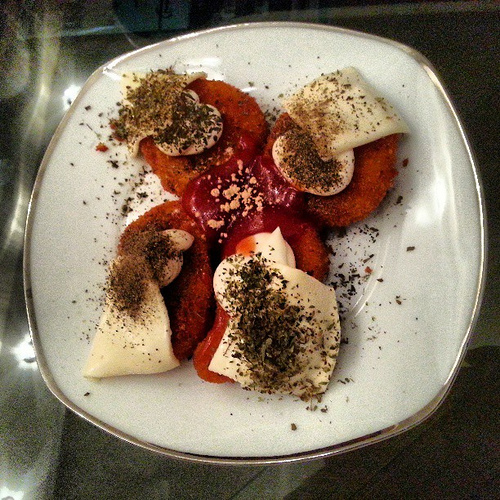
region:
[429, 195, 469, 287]
this is a plate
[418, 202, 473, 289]
the plate is glass like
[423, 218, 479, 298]
the plate is white incolor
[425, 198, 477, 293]
the plate is flat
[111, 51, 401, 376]
this is food on the plate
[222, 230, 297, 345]
the cream is white in color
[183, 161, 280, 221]
the spice is red in color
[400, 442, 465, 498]
this is the table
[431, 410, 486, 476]
the table is grey in color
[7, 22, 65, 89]
the table is glass like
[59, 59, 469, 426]
This is a dinner.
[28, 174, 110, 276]
The plate is white in color.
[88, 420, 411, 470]
The plate is trimmed with silver.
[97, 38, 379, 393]
this could be an appetizer.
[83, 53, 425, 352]
the plate is mostly full.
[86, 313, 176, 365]
this part of the food is white.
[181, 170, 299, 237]
This part of the food is white and red.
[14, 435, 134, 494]
The backdrop is green.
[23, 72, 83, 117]
This part of the backdrop is shiny.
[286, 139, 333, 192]
This part of the food is brown.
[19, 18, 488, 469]
a white dish with food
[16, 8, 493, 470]
border of dish is color silver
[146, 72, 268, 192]
piece of carrot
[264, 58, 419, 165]
cheese over a piece of carrot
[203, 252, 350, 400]
spices over a piece of cheese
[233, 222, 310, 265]
cream over a slice of carrot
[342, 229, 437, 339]
spices over a dish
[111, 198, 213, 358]
slice of carrot under a piece of cheese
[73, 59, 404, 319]
black pepper dusted over the food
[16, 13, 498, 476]
shape of dish is square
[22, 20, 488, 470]
a white plate with a silver edge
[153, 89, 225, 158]
dry herbs on a piece of mozzarella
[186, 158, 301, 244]
red sauce in the middle of a plate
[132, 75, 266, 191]
a slice of tomato on a white plate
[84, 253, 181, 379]
a slice of white cheese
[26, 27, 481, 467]
a plate with tomatoes and cheese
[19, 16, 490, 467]
a white plate on a green surface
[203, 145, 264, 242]
grated cheese on some red sauce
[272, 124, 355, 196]
a bit of mozzarella cheese on a tomato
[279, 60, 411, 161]
dry herbs on a slice of cheese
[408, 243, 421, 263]
spice on the plate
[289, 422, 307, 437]
spice on the plate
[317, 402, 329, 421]
spice on the plate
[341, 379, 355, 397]
spice on the plate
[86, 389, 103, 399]
spice on the plate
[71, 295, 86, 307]
spice on the plate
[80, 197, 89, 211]
spice on the plate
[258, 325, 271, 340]
spice on the plate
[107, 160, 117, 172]
spice on the plate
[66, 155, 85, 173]
spice on the plate